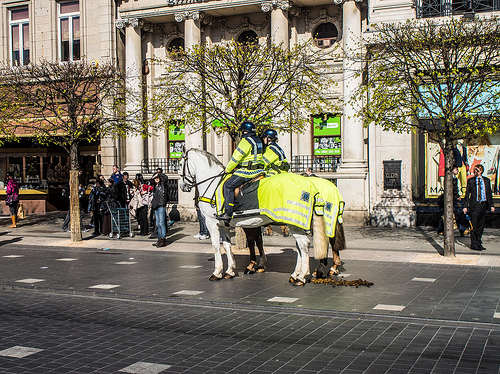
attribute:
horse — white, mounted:
[179, 143, 332, 286]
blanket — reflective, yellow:
[216, 172, 325, 232]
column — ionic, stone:
[116, 18, 151, 174]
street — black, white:
[3, 248, 499, 373]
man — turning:
[463, 162, 494, 250]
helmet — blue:
[238, 120, 258, 134]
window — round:
[310, 21, 340, 48]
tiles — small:
[1, 243, 499, 309]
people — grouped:
[86, 166, 171, 248]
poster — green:
[312, 118, 342, 157]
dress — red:
[440, 146, 449, 166]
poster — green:
[167, 117, 188, 160]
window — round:
[164, 36, 187, 62]